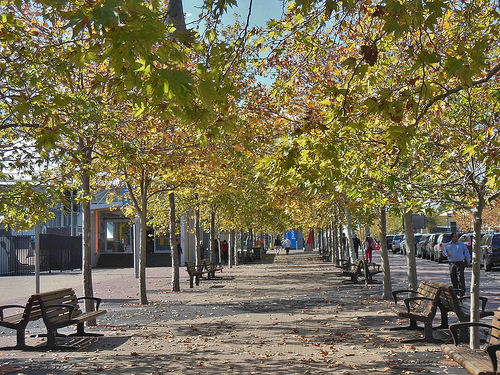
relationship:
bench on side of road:
[361, 259, 382, 283] [350, 245, 499, 316]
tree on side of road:
[339, 1, 428, 301] [350, 245, 499, 316]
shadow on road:
[397, 266, 489, 300] [350, 245, 499, 316]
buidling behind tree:
[1, 133, 194, 268] [109, 34, 166, 306]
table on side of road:
[249, 245, 264, 259] [350, 245, 499, 316]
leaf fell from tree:
[364, 294, 380, 306] [339, 1, 428, 301]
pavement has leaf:
[85, 251, 462, 374] [364, 294, 380, 306]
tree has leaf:
[109, 34, 166, 306] [144, 67, 198, 108]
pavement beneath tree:
[85, 251, 462, 374] [339, 1, 428, 301]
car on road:
[416, 235, 430, 262] [350, 245, 499, 316]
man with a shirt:
[444, 231, 471, 293] [443, 240, 470, 263]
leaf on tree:
[144, 67, 198, 108] [109, 34, 166, 306]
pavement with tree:
[85, 251, 462, 374] [339, 1, 428, 301]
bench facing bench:
[340, 259, 360, 285] [185, 261, 207, 291]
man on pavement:
[444, 231, 471, 293] [85, 251, 462, 374]